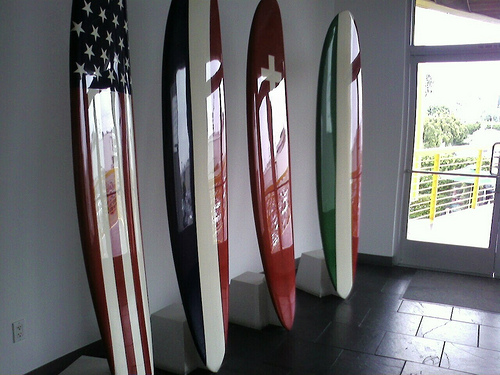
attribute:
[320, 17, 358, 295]
graphic — Italian flag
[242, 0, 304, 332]
surfboard — displayed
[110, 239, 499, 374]
floor — tile, black tile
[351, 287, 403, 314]
tile — grey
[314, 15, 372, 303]
surfboard — red, white, green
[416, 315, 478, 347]
tile — grey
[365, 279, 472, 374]
tile — deep brown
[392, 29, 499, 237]
glass — metal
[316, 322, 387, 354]
tile — grey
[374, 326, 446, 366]
tile — grey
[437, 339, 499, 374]
tile — grey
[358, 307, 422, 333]
tile — grey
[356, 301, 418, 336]
tile — grey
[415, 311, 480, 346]
tile — grey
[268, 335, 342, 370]
tile — grey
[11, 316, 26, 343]
electrical outlet — white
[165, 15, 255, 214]
blue surfboard — white, red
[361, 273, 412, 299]
tile — grey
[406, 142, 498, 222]
guard rail — yellow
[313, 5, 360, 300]
surfboard — green, white, red, new, shiney, four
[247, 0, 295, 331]
surfboard — shiney, new, swiss flag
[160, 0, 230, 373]
surfboard — red, white, and blue, shiney, new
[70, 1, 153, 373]
surfboard — US flag design, shiney, new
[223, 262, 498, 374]
tiled floor — grey , square, tile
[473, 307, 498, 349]
tile — grey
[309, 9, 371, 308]
surfboard — green 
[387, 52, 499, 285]
door — outdoor exit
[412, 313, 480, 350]
tile — grey, square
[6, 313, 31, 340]
outlet — electrical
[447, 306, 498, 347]
tile — grey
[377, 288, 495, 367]
tile — grey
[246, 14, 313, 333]
surfboard — red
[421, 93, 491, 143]
trees — distant